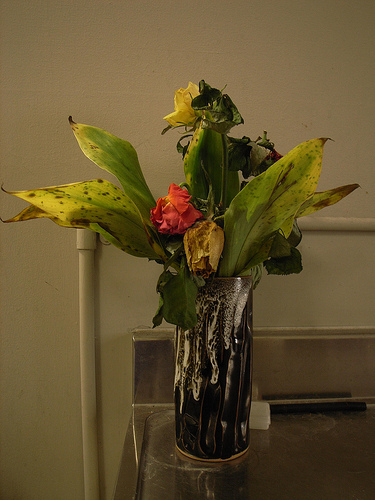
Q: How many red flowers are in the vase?
A: One.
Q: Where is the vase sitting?
A: On a counter.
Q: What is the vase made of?
A: Glass.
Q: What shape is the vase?
A: Round.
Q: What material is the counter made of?
A: Metal.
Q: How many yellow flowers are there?
A: One.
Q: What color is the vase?
A: Transparent.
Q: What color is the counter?
A: Silver.